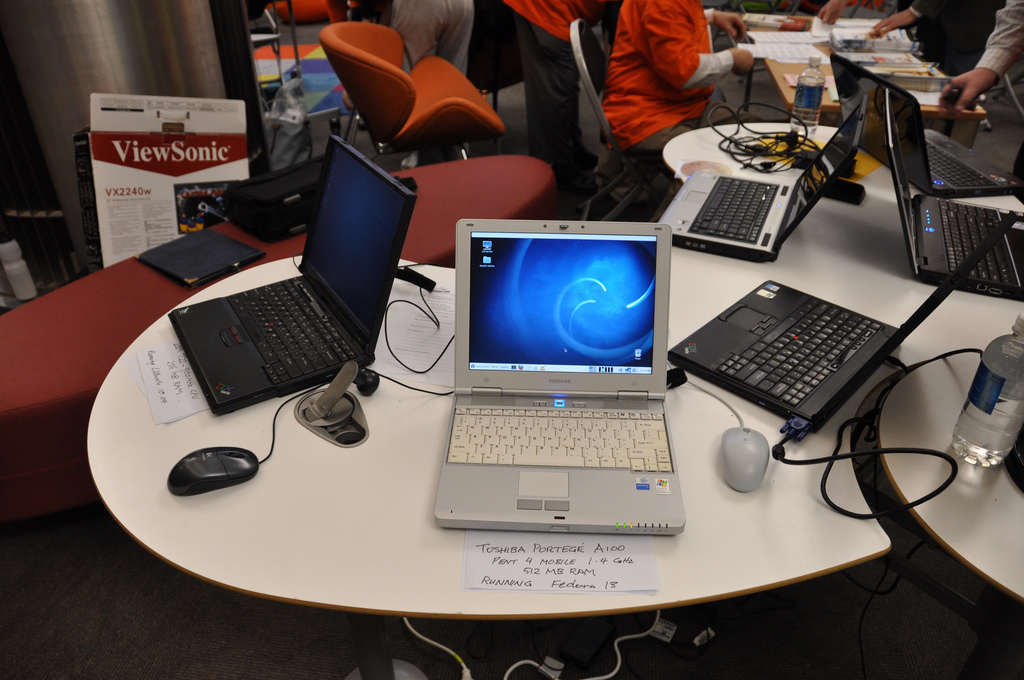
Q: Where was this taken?
A: Office.